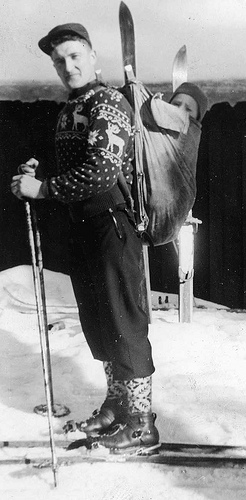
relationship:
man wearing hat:
[11, 17, 159, 456] [34, 21, 90, 50]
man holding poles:
[11, 17, 159, 456] [17, 160, 74, 487]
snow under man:
[1, 259, 244, 497] [11, 17, 159, 456]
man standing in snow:
[11, 17, 159, 456] [1, 259, 244, 497]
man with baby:
[11, 17, 159, 456] [167, 79, 207, 122]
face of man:
[54, 50, 83, 86] [11, 17, 159, 456]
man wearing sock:
[11, 17, 159, 456] [125, 377, 154, 411]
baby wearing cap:
[167, 79, 207, 122] [177, 79, 211, 113]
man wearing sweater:
[11, 17, 159, 456] [38, 83, 135, 215]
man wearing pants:
[11, 17, 159, 456] [68, 203, 157, 381]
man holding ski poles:
[11, 17, 159, 456] [18, 164, 81, 485]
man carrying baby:
[11, 17, 159, 456] [167, 79, 207, 122]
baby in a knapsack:
[167, 79, 207, 122] [121, 65, 200, 249]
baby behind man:
[167, 79, 207, 122] [11, 17, 159, 456]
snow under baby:
[1, 259, 244, 497] [167, 79, 207, 122]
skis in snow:
[17, 160, 74, 487] [2, 307, 239, 494]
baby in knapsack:
[167, 79, 207, 122] [118, 65, 207, 250]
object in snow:
[176, 208, 193, 322] [1, 259, 244, 497]